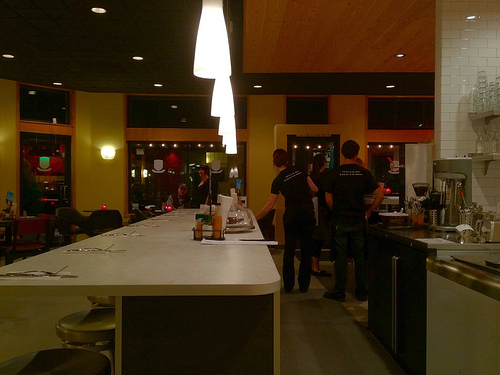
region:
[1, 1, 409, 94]
Lights on the ceiling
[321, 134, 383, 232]
Man wearing a black shirt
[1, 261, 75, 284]
Utensils on the countertop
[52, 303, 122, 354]
A round bar stool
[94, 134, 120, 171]
A bright light on the wall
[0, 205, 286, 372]
A long bar table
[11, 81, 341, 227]
Large windows on the wall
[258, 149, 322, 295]
A bartender wearing all black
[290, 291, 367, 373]
A shadow on the floor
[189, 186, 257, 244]
Many items on the table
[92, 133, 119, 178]
Light handing on the wall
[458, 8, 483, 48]
REflection in the tiles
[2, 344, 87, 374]
Top of silver bar stool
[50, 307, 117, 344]
Top of silver bar stool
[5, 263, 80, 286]
Silverware sitting on the counter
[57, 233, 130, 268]
Silverware sitting on the counter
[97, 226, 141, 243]
Silverware sitting on the counter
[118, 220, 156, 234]
Silverware sitting on the counter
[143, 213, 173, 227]
Silverware sitting on the counter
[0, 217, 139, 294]
Silverware sitting on the counter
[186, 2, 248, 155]
white lights hanging over bar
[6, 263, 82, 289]
fork laying on countertop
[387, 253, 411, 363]
silver colored handles on cabinet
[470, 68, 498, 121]
clear glasses on shelf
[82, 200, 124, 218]
red candle on table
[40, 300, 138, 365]
bar stool under bar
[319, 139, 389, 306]
man wearing a black shirt with white writing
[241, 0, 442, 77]
reddish colored wood paneling on ceiling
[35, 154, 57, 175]
coffee cup design on glass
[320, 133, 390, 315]
man wearing blue jeans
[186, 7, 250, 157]
A row of lights hanging from the ceiling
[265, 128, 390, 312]
Two kitchen workers behind the counter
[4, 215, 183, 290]
A row of silverware on the counter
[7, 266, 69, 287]
White napkins beneath the silverware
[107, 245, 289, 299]
A plain white counter top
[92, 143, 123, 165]
A globular light on the wall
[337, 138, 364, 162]
The man has short hair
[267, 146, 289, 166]
The woman has short hair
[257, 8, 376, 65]
The ceiling is made of wood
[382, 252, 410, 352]
Two metal bars on the cabinets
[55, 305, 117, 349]
metal stool under the counter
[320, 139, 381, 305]
back of a man standing in the kitchen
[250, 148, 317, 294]
woman in the kitchen leaning to the left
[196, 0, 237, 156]
light fixture on the ceiling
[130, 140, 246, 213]
window inside the restaurant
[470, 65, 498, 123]
counter with glass cups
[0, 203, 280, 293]
long white counter in a restaurant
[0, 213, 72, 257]
table with seating in a restaurant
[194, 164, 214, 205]
woman in black standing next to a window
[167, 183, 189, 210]
man sitting down in the restauran